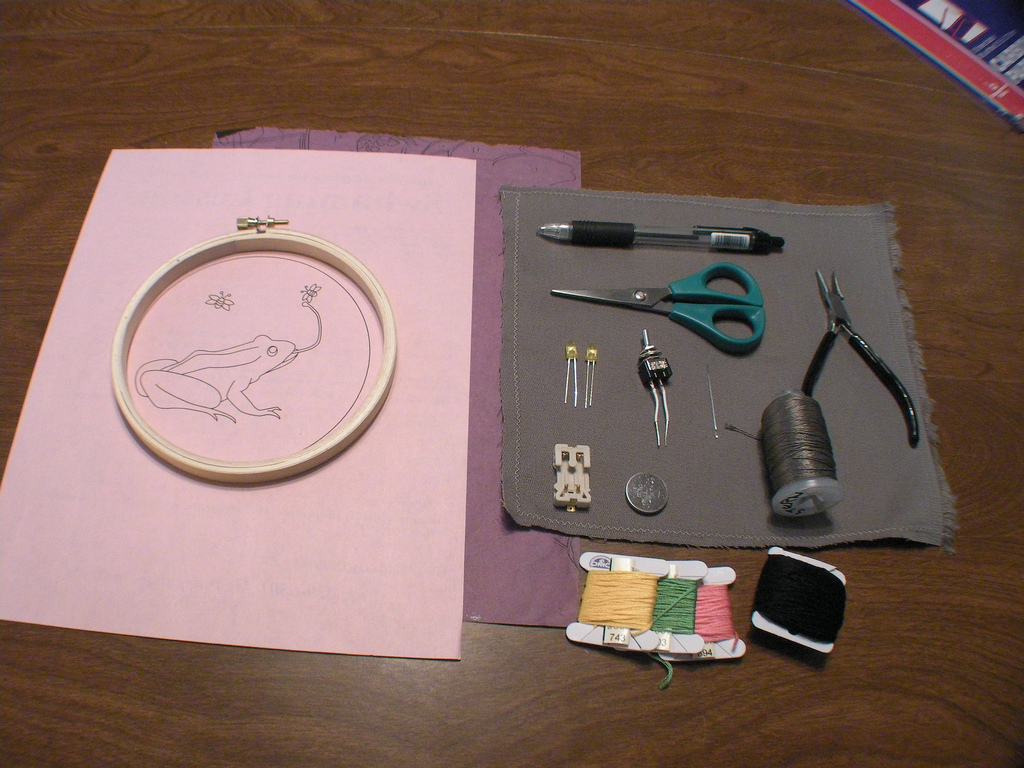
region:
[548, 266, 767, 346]
pair of scissors on the cloth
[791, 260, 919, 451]
black and silver pliers on the cloth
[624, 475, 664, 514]
silver coin on the cloth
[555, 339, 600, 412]
two small resistors on the cloth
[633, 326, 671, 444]
small electrical switch on the cloth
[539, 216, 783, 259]
black ink pen on the cloth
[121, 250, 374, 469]
drawing of a frog eating a fly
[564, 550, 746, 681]
rolls of different color string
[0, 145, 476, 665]
piece of pink paper on the table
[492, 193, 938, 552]
gray piece of cloth with various items on it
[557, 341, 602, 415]
small pair of resistors on the cloth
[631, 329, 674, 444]
small electronics switch on the cloth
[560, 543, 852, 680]
rolls on various colors of string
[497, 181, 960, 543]
grey cloth sewing kit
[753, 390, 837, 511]
roll of grey wire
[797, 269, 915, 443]
wire cutters with black handle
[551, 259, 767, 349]
sewing scissors with blue handle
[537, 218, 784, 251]
clear plastic pen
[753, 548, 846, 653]
pack of black thread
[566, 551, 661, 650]
pack of yellow thread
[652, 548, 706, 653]
pack of green thread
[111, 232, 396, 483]
wood ring over embroidered frog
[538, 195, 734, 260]
tool on the table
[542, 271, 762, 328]
tool on the table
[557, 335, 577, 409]
tool on the table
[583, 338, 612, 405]
tool on the table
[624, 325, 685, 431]
tool on the table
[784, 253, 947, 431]
tool on the table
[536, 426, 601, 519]
tool on the table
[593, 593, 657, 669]
tool on the table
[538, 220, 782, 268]
tool on the table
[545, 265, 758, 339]
tool on the table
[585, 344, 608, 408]
tool on the table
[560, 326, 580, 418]
tool on the table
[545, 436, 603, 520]
tool on the table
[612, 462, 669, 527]
tool on the table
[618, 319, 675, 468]
tool on the table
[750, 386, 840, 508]
tool on the table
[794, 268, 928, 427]
tool on the table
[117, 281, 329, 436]
frog eating a fly on pink paper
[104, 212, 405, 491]
embroidery ring encircling frog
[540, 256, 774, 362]
scissors with green handles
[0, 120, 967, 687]
collection of sewing items on table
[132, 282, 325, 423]
Sketch of a frog catching bugs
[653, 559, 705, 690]
Green thread thread for embroidery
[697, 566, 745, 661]
Pink embroidery thread on a white card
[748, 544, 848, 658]
White thread for needlework wrapped around a white card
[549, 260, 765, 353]
Small pair of scissors with blue-green handles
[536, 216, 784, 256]
Ballpoint pen with black ink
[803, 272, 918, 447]
Pair of needle nose pliers with black handles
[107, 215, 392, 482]
Small white embroidery hoop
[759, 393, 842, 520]
A roll of silver thread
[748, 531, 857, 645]
floss on the cardboard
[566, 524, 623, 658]
floss on the cardboard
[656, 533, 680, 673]
floss on the cardboard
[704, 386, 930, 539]
thread on the spool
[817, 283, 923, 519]
a tool on the mat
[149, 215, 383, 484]
a wooden embroidery ring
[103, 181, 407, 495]
frame around picture of a frog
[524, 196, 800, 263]
clear and black pen